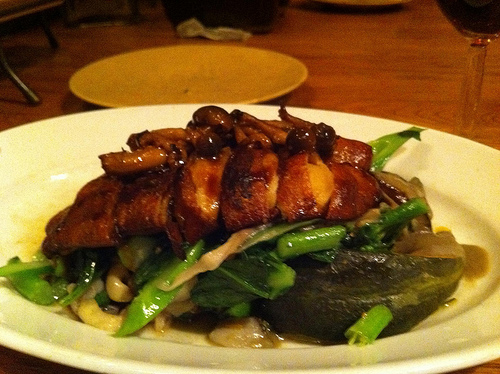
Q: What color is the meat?
A: Brown.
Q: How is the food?
A: Cooked.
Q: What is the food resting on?
A: A plate.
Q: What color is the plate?
A: White.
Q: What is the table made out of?
A: Wood.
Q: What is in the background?
A: Another plate.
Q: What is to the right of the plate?
A: A glass.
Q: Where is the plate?
A: On a table.